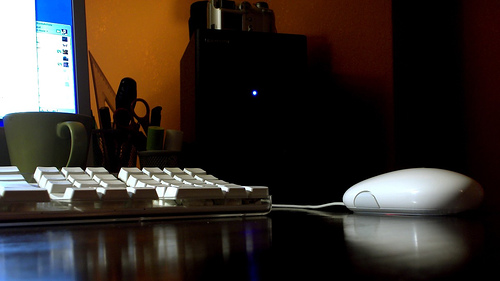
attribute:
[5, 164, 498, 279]
desk — black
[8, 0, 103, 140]
screen — on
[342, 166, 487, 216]
mouse — white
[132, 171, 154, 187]
key — white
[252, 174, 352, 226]
cord — white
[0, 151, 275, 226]
keyboard — white, plastic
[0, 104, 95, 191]
mug — white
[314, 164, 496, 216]
mouse — white, grey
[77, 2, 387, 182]
wall — yellow